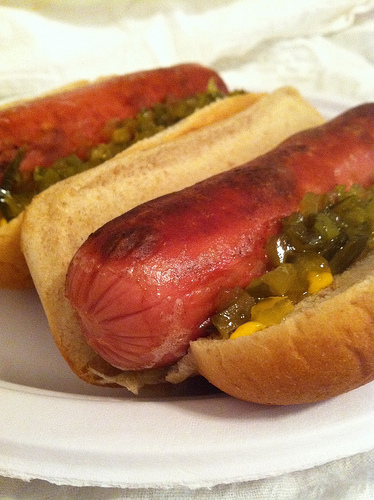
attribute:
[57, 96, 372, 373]
hotdogs — cooked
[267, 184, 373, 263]
relish — green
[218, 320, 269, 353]
mustard — yellow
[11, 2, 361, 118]
napkin — wrinkled